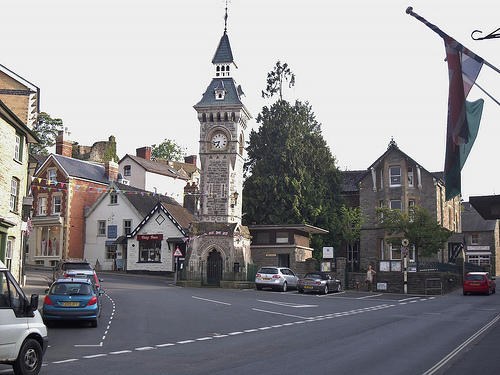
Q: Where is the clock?
A: On the tower.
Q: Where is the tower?
A: Across the road.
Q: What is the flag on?
A: A pole.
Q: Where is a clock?
A: On the tower.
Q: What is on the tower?
A: A clock.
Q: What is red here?
A: A car.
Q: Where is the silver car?
A: Parked.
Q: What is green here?
A: The trees.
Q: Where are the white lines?
A: On the street.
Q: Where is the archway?
A: On the tower.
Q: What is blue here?
A: Car.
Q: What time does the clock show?
A: 8:35.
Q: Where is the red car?
A: Street on the left.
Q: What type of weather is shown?
A: Clear.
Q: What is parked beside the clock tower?
A: A silver car and a gray car.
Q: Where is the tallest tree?
A: Behind the clock tower.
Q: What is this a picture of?
A: A European village.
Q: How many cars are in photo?
A: Six.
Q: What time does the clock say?
A: 8:35.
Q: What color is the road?
A: Black.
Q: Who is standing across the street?
A: A woman.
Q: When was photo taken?
A: In the daytime.